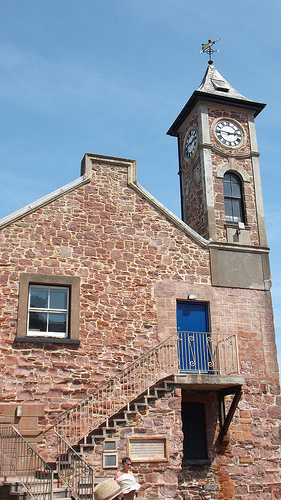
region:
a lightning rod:
[198, 37, 221, 63]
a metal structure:
[39, 334, 240, 426]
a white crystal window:
[28, 285, 68, 335]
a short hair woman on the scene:
[115, 457, 136, 496]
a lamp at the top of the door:
[187, 293, 196, 297]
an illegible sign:
[127, 435, 165, 457]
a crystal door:
[176, 300, 208, 369]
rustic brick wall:
[79, 276, 147, 350]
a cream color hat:
[88, 479, 129, 496]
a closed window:
[179, 402, 207, 463]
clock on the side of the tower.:
[212, 115, 246, 148]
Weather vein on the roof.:
[199, 36, 222, 66]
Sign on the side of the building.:
[123, 433, 170, 465]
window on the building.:
[219, 164, 249, 232]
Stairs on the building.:
[2, 331, 246, 498]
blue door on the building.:
[175, 295, 215, 377]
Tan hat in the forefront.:
[91, 478, 131, 499]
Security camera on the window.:
[234, 220, 246, 235]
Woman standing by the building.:
[114, 452, 138, 482]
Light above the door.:
[187, 293, 197, 299]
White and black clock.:
[212, 116, 247, 151]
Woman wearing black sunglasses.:
[112, 457, 142, 489]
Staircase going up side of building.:
[8, 333, 241, 495]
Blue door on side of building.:
[175, 299, 211, 375]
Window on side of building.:
[16, 272, 86, 352]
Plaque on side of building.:
[129, 436, 170, 463]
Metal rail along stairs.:
[81, 332, 246, 425]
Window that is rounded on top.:
[219, 167, 248, 226]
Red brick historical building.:
[6, 62, 279, 491]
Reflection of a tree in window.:
[23, 282, 69, 346]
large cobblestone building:
[0, 67, 280, 498]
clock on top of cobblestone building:
[212, 119, 245, 147]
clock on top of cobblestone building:
[180, 127, 200, 155]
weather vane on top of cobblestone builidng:
[199, 36, 223, 66]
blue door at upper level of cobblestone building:
[175, 300, 211, 373]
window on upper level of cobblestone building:
[28, 283, 70, 334]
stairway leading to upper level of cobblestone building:
[0, 331, 246, 498]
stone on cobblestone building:
[121, 295, 136, 307]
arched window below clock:
[221, 171, 245, 224]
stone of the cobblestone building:
[74, 356, 90, 365]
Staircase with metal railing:
[0, 330, 241, 499]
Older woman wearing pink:
[115, 455, 136, 498]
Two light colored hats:
[91, 472, 139, 498]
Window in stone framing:
[14, 271, 81, 344]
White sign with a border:
[126, 434, 169, 463]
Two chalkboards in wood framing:
[102, 437, 118, 469]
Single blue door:
[175, 297, 211, 374]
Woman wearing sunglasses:
[115, 454, 135, 498]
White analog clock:
[211, 117, 244, 148]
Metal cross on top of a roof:
[200, 38, 218, 62]